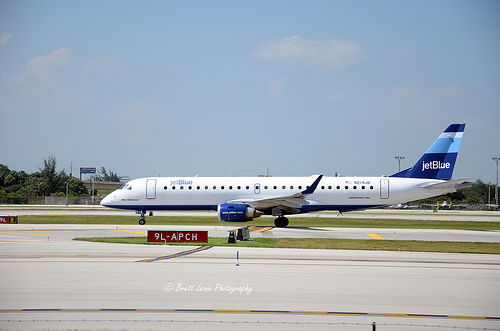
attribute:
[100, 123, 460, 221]
airplane — white, blue, heavy, large, huge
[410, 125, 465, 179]
stripes on tail — blue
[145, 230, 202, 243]
sign — red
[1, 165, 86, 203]
trees — green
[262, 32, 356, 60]
cloud — white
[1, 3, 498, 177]
sky — blue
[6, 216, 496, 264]
runway — cement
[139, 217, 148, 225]
tire — black